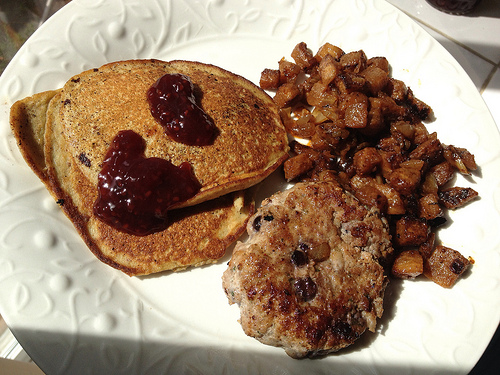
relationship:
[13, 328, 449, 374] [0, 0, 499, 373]
shadow on plate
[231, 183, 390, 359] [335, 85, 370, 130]
sausage next to hashbrown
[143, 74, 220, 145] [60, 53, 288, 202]
jam on pancake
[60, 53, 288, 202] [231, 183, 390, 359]
pancake next to sausage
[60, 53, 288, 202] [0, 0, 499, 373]
pancake on white plate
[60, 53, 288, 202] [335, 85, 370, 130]
pancake next to hashbrown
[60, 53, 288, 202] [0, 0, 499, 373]
pancake on plate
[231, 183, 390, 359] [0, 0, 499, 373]
sausage on plate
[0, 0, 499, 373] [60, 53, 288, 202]
plate of pancake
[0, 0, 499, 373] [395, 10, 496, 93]
plate on tile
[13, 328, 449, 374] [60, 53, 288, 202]
shadow by pancake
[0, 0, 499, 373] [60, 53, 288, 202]
plate with a pancake